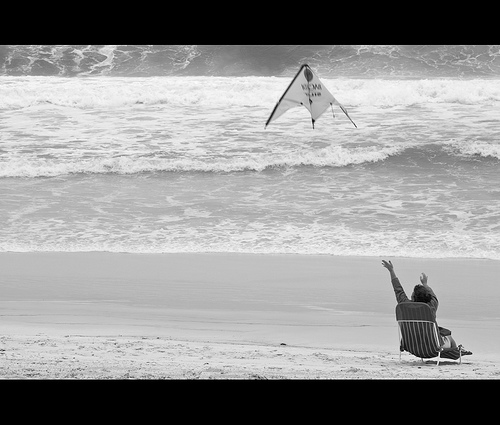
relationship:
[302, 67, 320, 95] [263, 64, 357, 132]
logo on kite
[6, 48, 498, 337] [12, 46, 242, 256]
wavy ocean filled with water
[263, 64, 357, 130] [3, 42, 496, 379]
kite on beach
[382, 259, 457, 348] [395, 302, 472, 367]
person sitting in chair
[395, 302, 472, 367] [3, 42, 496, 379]
chair on beach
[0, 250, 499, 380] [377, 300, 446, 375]
beach has chair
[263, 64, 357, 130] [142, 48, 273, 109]
kite in sky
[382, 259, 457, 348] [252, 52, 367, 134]
person flies kite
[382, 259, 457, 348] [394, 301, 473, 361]
person sits in chair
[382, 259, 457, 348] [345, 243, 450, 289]
person waves hands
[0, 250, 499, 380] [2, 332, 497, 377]
beach has sand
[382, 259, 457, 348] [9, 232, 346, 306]
person sits near shore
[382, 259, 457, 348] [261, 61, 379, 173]
person watches kite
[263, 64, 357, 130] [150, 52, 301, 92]
kite in sky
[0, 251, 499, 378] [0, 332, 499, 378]
sand has footprints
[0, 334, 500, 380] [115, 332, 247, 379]
sand has footprints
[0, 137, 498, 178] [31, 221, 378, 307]
waves crash on shore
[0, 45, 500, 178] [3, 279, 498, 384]
waves crash on shore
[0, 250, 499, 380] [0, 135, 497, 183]
beach has waves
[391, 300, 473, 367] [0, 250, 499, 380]
chair on beach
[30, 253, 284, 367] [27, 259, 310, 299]
beach has wet sand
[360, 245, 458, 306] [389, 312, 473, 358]
person sits in chair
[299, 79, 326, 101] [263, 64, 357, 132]
letters on kite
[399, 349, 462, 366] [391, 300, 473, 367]
metal leg on chair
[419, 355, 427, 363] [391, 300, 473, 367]
metal leg on chair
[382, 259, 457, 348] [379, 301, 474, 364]
person on chair